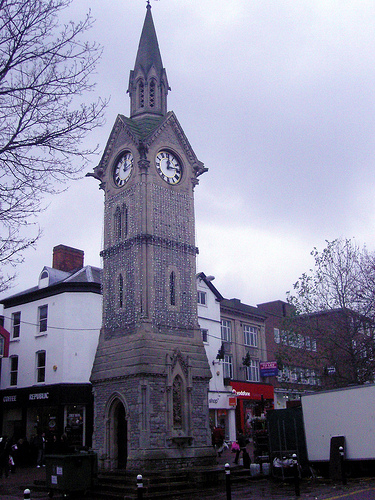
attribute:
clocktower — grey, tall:
[83, 2, 222, 468]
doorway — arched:
[102, 387, 136, 471]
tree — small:
[278, 231, 375, 389]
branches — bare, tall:
[0, 0, 105, 307]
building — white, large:
[0, 241, 96, 459]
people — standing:
[2, 421, 71, 453]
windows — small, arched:
[108, 201, 187, 324]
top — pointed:
[130, 1, 168, 118]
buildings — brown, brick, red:
[216, 279, 374, 383]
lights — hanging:
[104, 182, 196, 330]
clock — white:
[105, 149, 139, 189]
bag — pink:
[229, 441, 243, 455]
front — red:
[225, 375, 278, 446]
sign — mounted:
[257, 358, 281, 380]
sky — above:
[205, 0, 373, 240]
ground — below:
[3, 470, 368, 499]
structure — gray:
[293, 384, 375, 470]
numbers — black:
[116, 155, 132, 161]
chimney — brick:
[49, 243, 93, 273]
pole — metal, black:
[221, 460, 244, 499]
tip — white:
[220, 460, 234, 470]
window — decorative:
[130, 73, 167, 114]